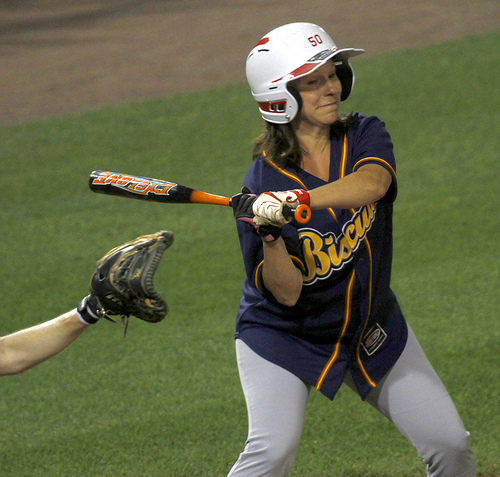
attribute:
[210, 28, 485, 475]
person — baseball player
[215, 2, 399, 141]
helmet — white, red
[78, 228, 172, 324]
hand — catcher's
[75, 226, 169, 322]
mitt — catcher's, black, tan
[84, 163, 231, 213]
bat — orange, black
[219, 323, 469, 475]
pants — white, baseball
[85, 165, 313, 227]
bat — softball, orange and black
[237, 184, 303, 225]
gloves — batter's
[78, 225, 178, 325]
mitt —  catcher's,  hand's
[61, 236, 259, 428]
glove — black, leather, catcher's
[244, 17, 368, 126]
helmet — white and red, batter's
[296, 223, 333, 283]
b — yellow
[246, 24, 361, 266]
player —  batter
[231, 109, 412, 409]
jersey — navy, yellow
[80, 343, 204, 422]
grass — green, manicured